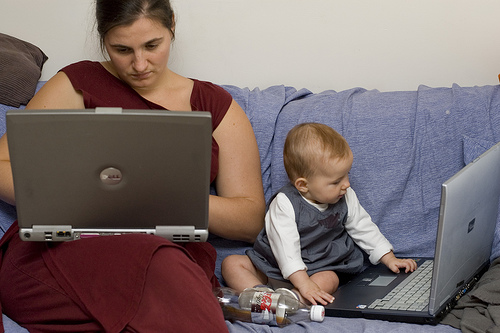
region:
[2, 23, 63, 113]
gray throw pillow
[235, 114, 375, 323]
baby girl in denim dress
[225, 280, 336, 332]
empty soft drink bottle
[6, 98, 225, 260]
gray laptop computer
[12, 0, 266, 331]
lady in burgundy dress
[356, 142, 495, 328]
silver laptop computer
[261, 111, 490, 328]
baby girl playing on laptop computer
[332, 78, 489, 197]
blue throw blanket on back of couch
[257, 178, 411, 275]
baby long sleeve white shirt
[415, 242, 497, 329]
gray thrown blanket sitting on couch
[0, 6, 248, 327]
a woman in a red dress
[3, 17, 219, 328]
a laptop is open on her lap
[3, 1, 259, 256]
the lady is working on her laptop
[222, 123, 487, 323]
a child is playing on a laptop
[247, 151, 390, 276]
teh child has a gray and white outfit on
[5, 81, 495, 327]
the couch has a blue cover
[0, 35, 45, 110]
a brown pillow is on the back of the couch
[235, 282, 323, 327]
a plastic bottle is lying on the couch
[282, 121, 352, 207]
the baby's hair is golden brown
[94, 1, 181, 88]
the lady's hair is dark brown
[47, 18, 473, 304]
mother and child using laptops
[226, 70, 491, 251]
blue fabric draped over back of sofa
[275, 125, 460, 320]
baby's hands near keyboard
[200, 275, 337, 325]
bottle of soda laying on sofa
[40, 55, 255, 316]
mother wearing red draped outfit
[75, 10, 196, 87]
woman looking down at laptop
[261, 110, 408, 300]
baby wearing jumper with white shirt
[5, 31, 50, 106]
brown pillow near woman's shoulder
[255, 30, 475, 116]
light grey wall behind sofa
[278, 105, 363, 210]
brown hair swept over baby's head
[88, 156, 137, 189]
Dell computers logo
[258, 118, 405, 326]
A baby looking at a computer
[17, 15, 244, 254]
A woman looking at a computer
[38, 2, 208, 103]
A woman looking down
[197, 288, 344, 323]
A mostly empty diet coke bottle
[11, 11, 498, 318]
A family sitting on couch using computers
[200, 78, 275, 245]
A human arm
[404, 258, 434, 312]
A computer keyboard on laptop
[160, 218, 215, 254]
Air relief vent for lap top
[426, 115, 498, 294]
Laptop lid in open position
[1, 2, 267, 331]
woman sitting on couch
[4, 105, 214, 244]
grey Dell laptop in woman's lap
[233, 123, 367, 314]
child sitting on couch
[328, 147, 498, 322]
laptop sitting on the couch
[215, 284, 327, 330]
almost empty plastic Coke bottle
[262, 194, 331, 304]
right arm of child on couch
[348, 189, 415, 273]
left arm of child on couch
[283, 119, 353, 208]
head of child on couch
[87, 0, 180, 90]
head of woman on couch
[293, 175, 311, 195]
right ear of child on couch